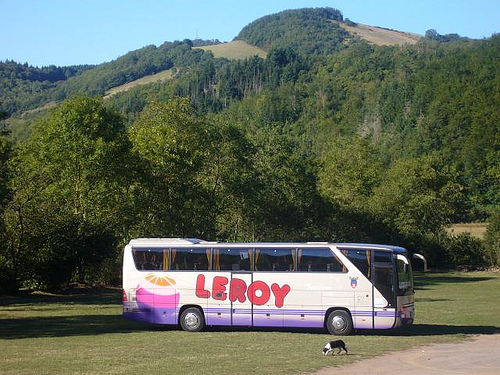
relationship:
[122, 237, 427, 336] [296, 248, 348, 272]
bus with windows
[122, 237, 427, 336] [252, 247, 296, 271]
bus with windows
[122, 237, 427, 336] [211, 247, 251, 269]
bus with windows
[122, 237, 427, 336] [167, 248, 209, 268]
bus with windows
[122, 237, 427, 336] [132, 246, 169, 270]
bus with windows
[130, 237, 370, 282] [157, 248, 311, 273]
windows have curtains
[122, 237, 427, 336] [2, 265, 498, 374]
bus parked on grass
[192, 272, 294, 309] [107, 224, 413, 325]
word on side of bus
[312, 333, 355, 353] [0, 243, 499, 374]
dog on grass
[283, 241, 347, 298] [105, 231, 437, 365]
windows on bus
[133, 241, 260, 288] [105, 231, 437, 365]
windows on bus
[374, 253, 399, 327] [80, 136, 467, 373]
door on bus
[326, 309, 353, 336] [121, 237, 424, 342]
wheels on bus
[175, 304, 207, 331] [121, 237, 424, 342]
wheels on bus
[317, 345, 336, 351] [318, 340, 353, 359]
markings on dog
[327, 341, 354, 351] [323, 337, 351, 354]
markings on dog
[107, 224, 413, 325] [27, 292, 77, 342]
bus casting a shadow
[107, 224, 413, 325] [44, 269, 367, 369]
bus parked in a field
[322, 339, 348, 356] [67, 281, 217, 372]
dog standing in field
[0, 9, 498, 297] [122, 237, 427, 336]
trees behind bus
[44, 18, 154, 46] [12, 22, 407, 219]
skies over scene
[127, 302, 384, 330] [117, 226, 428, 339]
stripes on bus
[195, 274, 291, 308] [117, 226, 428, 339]
logo on bus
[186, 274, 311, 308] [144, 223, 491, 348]
logo on bus